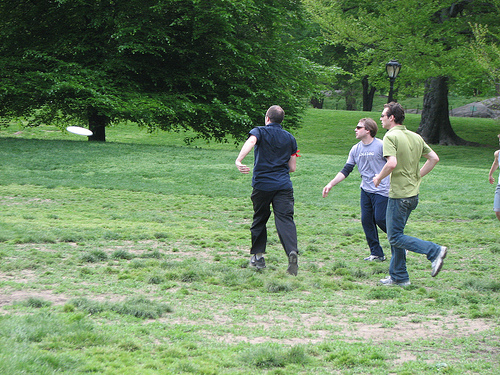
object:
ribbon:
[291, 150, 301, 158]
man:
[235, 105, 299, 278]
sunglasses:
[355, 125, 365, 130]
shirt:
[345, 137, 389, 198]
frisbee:
[66, 126, 93, 136]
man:
[489, 134, 500, 220]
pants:
[249, 182, 299, 254]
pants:
[360, 187, 388, 256]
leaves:
[0, 0, 354, 152]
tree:
[0, 0, 355, 145]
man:
[372, 101, 448, 288]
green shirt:
[382, 125, 432, 199]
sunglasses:
[381, 113, 390, 117]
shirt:
[248, 123, 298, 192]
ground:
[0, 88, 499, 375]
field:
[0, 103, 499, 374]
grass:
[0, 106, 499, 374]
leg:
[272, 187, 299, 250]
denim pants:
[386, 195, 441, 283]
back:
[254, 126, 298, 187]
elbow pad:
[339, 163, 355, 178]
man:
[322, 117, 393, 263]